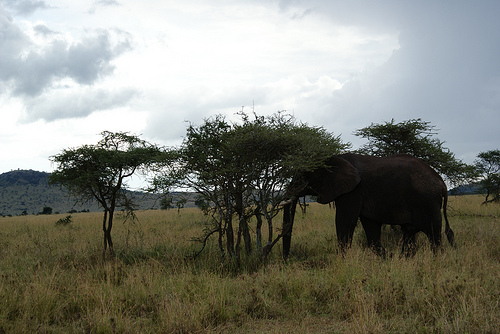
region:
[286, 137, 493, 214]
Elephant on the planes.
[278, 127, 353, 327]
Elephant looking for food.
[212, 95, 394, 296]
Elephant near the shrubs.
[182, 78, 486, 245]
African safari elephant watching.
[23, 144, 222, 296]
Hills in the background.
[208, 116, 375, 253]
Shrubs on the planes of Africa.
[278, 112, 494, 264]
Elephant walking along the Savannah.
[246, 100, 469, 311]
Dried grass on the planes.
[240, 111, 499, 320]
Elephant walking through the dried grass.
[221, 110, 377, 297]
Thorn bushes next to the elephant.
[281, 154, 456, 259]
elephant is looking into tree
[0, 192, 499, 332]
tall grass covers the savannah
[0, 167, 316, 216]
short hill is in background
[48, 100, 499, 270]
a group of four trees is near elephant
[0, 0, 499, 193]
sky is cloudy above trees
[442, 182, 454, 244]
long thin tail on elephant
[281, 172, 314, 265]
elephant has long trunk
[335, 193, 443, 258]
elephant has four legs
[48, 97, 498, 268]
trees are bushy and short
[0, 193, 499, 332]
flat ground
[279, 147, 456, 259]
large brown elephant near tree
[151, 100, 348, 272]
green tree in front of elephant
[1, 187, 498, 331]
green and brown grass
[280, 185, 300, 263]
long trunk of elephant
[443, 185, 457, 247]
long thin tail of elephant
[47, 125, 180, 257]
small green tree near elephant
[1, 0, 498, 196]
sky grey and cloudy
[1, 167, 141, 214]
large hill in distance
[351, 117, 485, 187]
green tree behind elephant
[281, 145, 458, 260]
elephant standing in tall grass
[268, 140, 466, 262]
elephant under a tree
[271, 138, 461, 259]
elephant is black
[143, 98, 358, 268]
tree over the elephant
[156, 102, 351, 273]
tree is small and green in the middle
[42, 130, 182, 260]
tiny tree to the left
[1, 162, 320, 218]
small mountain in the distance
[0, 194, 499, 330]
grass is dry looking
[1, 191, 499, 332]
grass is light green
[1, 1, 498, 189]
sky is cloudy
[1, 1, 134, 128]
clouds are gray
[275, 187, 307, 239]
large gray elephant tusk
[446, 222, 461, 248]
tip of elephant tail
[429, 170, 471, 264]
tall gray elephant tail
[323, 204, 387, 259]
large elephant feet in the grass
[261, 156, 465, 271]
large elephant grazing in the green grass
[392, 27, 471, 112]
dark clouds in the sky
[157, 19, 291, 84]
fluffy white clouds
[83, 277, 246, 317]
brown grass in the field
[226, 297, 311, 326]
sparse area in the grass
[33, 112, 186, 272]
large green tree with leaves